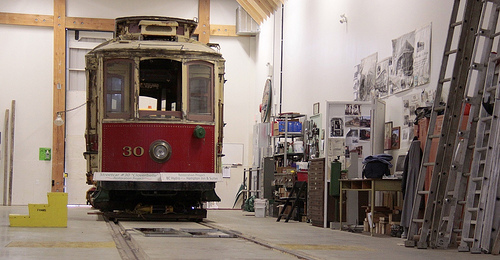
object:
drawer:
[308, 161, 323, 167]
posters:
[413, 21, 433, 87]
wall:
[0, 0, 257, 209]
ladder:
[405, 100, 450, 248]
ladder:
[457, 56, 500, 253]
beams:
[52, 0, 67, 192]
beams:
[197, 0, 210, 45]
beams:
[0, 12, 258, 37]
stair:
[47, 192, 67, 204]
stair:
[28, 203, 50, 217]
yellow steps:
[8, 214, 32, 227]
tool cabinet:
[306, 158, 325, 227]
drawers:
[308, 167, 322, 171]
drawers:
[308, 181, 322, 187]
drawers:
[306, 205, 321, 210]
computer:
[393, 151, 409, 174]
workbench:
[337, 178, 404, 237]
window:
[137, 58, 183, 111]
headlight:
[152, 144, 172, 161]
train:
[83, 15, 227, 209]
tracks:
[110, 218, 146, 259]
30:
[121, 145, 145, 157]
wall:
[255, 0, 499, 254]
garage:
[0, 0, 499, 259]